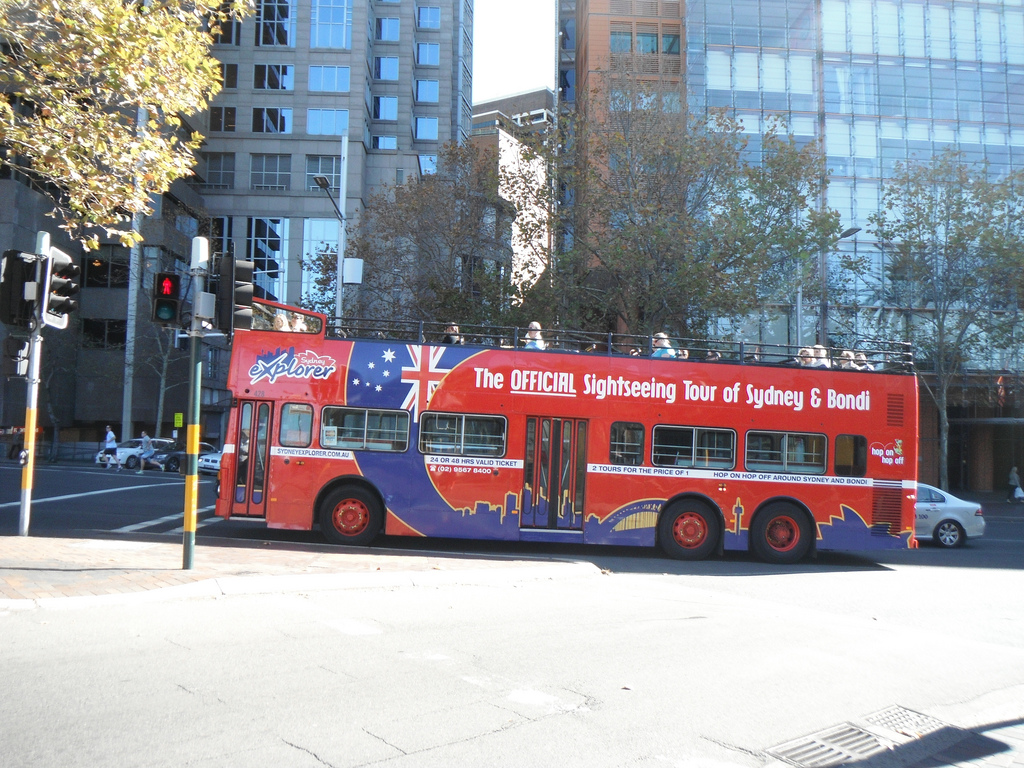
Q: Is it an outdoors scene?
A: Yes, it is outdoors.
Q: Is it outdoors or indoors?
A: It is outdoors.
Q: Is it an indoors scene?
A: No, it is outdoors.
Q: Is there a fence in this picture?
A: No, there are no fences.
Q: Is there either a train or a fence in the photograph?
A: No, there are no fences or trains.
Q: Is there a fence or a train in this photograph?
A: No, there are no fences or trains.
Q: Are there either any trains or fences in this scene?
A: No, there are no fences or trains.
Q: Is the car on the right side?
A: Yes, the car is on the right of the image.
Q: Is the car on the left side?
A: No, the car is on the right of the image.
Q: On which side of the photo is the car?
A: The car is on the right of the image.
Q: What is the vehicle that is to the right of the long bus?
A: The vehicle is a car.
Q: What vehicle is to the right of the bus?
A: The vehicle is a car.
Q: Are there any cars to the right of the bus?
A: Yes, there is a car to the right of the bus.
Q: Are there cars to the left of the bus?
A: No, the car is to the right of the bus.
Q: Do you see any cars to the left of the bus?
A: No, the car is to the right of the bus.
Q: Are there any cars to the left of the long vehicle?
A: No, the car is to the right of the bus.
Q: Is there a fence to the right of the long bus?
A: No, there is a car to the right of the bus.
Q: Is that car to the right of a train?
A: No, the car is to the right of the bus.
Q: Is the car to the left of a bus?
A: No, the car is to the right of a bus.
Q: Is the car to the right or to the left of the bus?
A: The car is to the right of the bus.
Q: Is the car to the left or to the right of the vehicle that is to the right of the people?
A: The car is to the right of the bus.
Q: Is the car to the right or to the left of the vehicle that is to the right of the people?
A: The car is to the right of the bus.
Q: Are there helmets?
A: No, there are no helmets.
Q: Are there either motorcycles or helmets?
A: No, there are no helmets or motorcycles.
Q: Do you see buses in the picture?
A: Yes, there is a bus.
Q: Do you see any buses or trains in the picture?
A: Yes, there is a bus.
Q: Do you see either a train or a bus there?
A: Yes, there is a bus.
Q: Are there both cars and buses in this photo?
A: Yes, there are both a bus and a car.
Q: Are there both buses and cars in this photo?
A: Yes, there are both a bus and a car.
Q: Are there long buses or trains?
A: Yes, there is a long bus.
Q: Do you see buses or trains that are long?
A: Yes, the bus is long.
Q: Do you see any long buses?
A: Yes, there is a long bus.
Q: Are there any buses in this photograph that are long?
A: Yes, there is a bus that is long.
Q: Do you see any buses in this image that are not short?
A: Yes, there is a long bus.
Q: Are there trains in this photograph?
A: No, there are no trains.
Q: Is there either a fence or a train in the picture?
A: No, there are no trains or fences.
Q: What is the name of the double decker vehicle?
A: The vehicle is a bus.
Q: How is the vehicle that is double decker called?
A: The vehicle is a bus.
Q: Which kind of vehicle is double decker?
A: The vehicle is a bus.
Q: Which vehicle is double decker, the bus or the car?
A: The bus is double decker.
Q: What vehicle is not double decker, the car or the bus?
A: The car is not double decker.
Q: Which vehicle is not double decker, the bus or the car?
A: The car is not double decker.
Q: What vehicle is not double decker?
A: The vehicle is a car.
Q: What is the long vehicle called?
A: The vehicle is a bus.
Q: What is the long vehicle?
A: The vehicle is a bus.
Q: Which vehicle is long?
A: The vehicle is a bus.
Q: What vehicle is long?
A: The vehicle is a bus.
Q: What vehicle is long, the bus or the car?
A: The bus is long.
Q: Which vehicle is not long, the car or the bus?
A: The car is not long.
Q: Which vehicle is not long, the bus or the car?
A: The car is not long.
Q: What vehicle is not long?
A: The vehicle is a car.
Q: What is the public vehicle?
A: The vehicle is a bus.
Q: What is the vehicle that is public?
A: The vehicle is a bus.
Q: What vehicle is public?
A: The vehicle is a bus.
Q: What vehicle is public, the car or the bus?
A: The bus is public.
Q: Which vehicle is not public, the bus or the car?
A: The car is not public.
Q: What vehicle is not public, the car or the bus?
A: The car is not public.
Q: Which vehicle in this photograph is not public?
A: The vehicle is a car.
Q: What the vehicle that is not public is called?
A: The vehicle is a car.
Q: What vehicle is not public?
A: The vehicle is a car.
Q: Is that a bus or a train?
A: That is a bus.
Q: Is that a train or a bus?
A: That is a bus.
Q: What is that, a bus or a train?
A: That is a bus.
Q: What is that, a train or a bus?
A: That is a bus.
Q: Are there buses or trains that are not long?
A: No, there is a bus but it is long.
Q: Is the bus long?
A: Yes, the bus is long.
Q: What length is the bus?
A: The bus is long.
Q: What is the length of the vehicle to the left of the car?
A: The bus is long.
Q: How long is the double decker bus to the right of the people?
A: The bus is long.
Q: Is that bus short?
A: No, the bus is long.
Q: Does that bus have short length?
A: No, the bus is long.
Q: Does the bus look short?
A: No, the bus is long.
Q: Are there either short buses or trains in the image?
A: No, there is a bus but it is long.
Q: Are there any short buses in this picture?
A: No, there is a bus but it is long.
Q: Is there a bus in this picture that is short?
A: No, there is a bus but it is long.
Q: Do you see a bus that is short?
A: No, there is a bus but it is long.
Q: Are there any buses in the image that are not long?
A: No, there is a bus but it is long.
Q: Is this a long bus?
A: Yes, this is a long bus.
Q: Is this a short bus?
A: No, this is a long bus.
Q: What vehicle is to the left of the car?
A: The vehicle is a bus.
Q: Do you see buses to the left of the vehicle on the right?
A: Yes, there is a bus to the left of the car.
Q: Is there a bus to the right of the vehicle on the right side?
A: No, the bus is to the left of the car.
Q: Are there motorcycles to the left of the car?
A: No, there is a bus to the left of the car.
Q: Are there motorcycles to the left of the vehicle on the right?
A: No, there is a bus to the left of the car.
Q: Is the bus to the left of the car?
A: Yes, the bus is to the left of the car.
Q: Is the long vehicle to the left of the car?
A: Yes, the bus is to the left of the car.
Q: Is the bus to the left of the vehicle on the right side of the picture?
A: Yes, the bus is to the left of the car.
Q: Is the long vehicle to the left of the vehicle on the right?
A: Yes, the bus is to the left of the car.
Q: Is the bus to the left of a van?
A: No, the bus is to the left of the car.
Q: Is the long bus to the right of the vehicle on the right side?
A: No, the bus is to the left of the car.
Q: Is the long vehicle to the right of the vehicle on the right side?
A: No, the bus is to the left of the car.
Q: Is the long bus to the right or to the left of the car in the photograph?
A: The bus is to the left of the car.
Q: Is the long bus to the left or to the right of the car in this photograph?
A: The bus is to the left of the car.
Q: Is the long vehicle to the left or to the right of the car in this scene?
A: The bus is to the left of the car.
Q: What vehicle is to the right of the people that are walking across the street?
A: The vehicle is a bus.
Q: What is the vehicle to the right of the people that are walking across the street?
A: The vehicle is a bus.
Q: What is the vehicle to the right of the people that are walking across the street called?
A: The vehicle is a bus.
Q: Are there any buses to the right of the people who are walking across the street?
A: Yes, there is a bus to the right of the people.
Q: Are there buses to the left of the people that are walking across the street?
A: No, the bus is to the right of the people.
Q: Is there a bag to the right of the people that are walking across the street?
A: No, there is a bus to the right of the people.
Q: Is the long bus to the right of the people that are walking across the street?
A: Yes, the bus is to the right of the people.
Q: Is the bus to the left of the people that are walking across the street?
A: No, the bus is to the right of the people.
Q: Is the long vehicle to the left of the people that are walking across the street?
A: No, the bus is to the right of the people.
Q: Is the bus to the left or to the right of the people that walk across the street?
A: The bus is to the right of the people.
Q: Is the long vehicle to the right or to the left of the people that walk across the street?
A: The bus is to the right of the people.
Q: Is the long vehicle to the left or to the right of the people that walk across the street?
A: The bus is to the right of the people.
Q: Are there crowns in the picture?
A: No, there are no crowns.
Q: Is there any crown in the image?
A: No, there are no crowns.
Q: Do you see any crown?
A: No, there are no crowns.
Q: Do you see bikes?
A: No, there are no bikes.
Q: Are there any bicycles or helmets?
A: No, there are no bicycles or helmets.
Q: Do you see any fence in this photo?
A: No, there are no fences.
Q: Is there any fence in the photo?
A: No, there are no fences.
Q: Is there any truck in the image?
A: No, there are no trucks.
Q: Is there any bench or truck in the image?
A: No, there are no trucks or benches.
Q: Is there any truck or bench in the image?
A: No, there are no trucks or benches.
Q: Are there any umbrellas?
A: No, there are no umbrellas.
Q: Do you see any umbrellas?
A: No, there are no umbrellas.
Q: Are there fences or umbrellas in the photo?
A: No, there are no umbrellas or fences.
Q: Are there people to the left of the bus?
A: Yes, there are people to the left of the bus.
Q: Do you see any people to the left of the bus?
A: Yes, there are people to the left of the bus.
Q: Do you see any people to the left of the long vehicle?
A: Yes, there are people to the left of the bus.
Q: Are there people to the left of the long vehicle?
A: Yes, there are people to the left of the bus.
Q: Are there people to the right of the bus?
A: No, the people are to the left of the bus.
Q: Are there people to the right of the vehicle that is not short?
A: No, the people are to the left of the bus.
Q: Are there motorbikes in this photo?
A: No, there are no motorbikes.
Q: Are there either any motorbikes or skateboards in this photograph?
A: No, there are no motorbikes or skateboards.